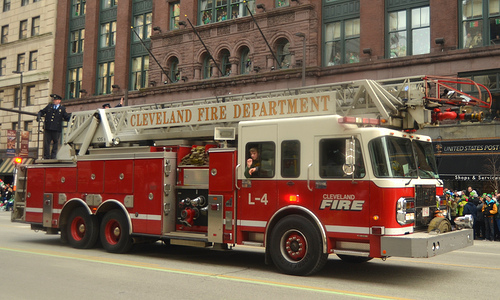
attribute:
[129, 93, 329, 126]
writing — yellow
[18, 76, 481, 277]
firetruck — red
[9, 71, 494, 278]
truck — red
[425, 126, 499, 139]
wall — tan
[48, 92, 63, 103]
hat — black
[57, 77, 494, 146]
ladder — white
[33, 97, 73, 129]
jacket — dark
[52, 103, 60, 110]
shirt — blue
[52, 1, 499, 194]
wall — brown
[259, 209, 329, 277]
wheel — black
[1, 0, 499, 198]
building — brown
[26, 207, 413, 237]
stripe — write